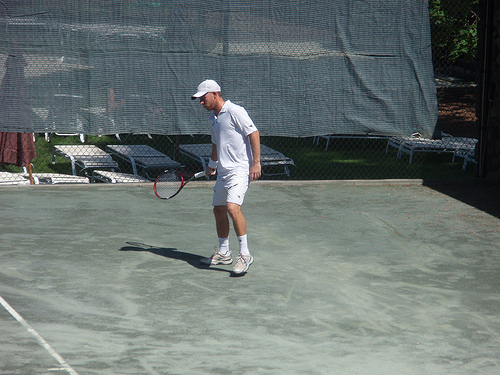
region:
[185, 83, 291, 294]
A man wearing white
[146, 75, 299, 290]
A man holding a tennia racket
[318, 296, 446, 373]
A grey smooth tennis court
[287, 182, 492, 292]
A grey smooth tennis court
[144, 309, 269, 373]
A grey smooth tennis court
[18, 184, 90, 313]
A grey smooth tennis court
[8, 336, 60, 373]
A grey smooth tennis court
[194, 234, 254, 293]
Nice grey sport shoes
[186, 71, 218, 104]
A white tennis cap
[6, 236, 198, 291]
A grey smooth tennis court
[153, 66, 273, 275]
a person holding tennis racket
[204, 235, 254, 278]
a person wearing pair of shoes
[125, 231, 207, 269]
shadow of the person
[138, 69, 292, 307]
a player standing in the tennis court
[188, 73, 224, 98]
a person wearing white color hat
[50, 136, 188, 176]
players rest place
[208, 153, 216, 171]
person wearing wrist band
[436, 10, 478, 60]
tree with branches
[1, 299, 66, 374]
tennis court marked with white color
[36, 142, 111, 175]
grass with wooden cot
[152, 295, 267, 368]
the turf is faded green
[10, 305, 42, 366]
a white line is on the ground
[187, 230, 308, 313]
a man is wearing tennis shoes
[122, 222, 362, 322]
the man's shadow is on the ground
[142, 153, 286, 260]
the racquet is red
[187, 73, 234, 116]
the man is wearing a white hat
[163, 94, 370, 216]
the man has a white shirt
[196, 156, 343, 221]
the man has white shorts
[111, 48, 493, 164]
a green net is behind the man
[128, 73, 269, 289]
A person holding the tennis racket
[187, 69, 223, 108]
A person wearing white color hat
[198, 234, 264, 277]
A person wearing white color pair of shoes and socks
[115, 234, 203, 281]
Shadow of the person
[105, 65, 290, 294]
A player standing in the tennis court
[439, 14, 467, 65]
Tree with green leaves and branches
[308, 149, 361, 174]
Green color grass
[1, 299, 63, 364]
Tennis court marked with white line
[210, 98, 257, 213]
A person wearing white color t-shirt and half trouser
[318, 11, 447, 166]
Green color net near the tennis court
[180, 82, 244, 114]
man has white hat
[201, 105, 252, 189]
man has white shirt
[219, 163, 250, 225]
man has white shorts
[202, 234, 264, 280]
man has white socks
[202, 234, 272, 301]
man has tan shoes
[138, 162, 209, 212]
red and black racket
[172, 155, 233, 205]
white grip on racket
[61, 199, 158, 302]
tennis court is grey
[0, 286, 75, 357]
white line on court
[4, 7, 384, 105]
grey tarp behind man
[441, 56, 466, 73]
green leaves on the tree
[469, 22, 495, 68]
green leaves on the tree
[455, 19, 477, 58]
green leaves on the tree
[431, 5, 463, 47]
green leaves on the tree